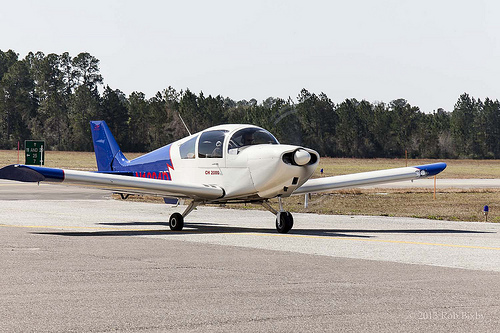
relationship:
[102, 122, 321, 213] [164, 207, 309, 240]
plane has wheels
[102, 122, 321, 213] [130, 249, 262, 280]
plane on top of ground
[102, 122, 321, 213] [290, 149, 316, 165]
plane has propeller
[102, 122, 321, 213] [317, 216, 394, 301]
plane on top of runway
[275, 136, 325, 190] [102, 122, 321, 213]
nose of plane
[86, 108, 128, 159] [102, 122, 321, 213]
tail of plane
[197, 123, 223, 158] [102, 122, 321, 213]
window attached to plane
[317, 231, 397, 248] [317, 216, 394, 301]
line on top of runway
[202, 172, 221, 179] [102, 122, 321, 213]
writing on plane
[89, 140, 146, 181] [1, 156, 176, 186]
blue on wing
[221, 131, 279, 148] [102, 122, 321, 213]
windshield on plane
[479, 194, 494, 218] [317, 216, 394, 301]
light on side of runway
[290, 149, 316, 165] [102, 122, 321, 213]
propeller attached to plane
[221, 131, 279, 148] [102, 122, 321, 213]
windshield on front of plane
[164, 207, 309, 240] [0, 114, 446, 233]
wheels on plane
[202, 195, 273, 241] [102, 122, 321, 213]
landing gear attached to plane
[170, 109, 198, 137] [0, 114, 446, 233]
antenna attached to plane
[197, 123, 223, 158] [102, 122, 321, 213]
window of plane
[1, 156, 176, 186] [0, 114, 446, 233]
wing of plane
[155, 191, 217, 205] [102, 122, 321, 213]
engine attached to plane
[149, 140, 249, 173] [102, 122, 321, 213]
windows attached to plane